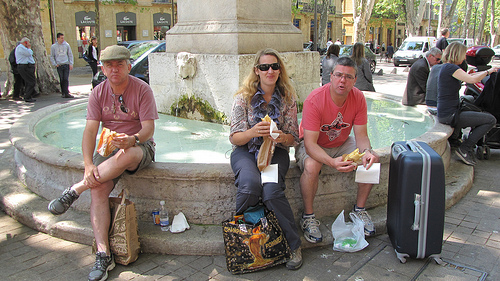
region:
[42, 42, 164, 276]
man in a rusty pink colored shirt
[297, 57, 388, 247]
man in a red shirt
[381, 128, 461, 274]
black and silver plastic suit case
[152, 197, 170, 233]
clear plastic bottle of water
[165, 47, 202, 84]
white stone lion head spitting water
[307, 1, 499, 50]
grouping of trees next to the street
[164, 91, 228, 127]
green algae growing on the fountain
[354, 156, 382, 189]
white paper napkin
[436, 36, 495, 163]
blonde lady wearing all black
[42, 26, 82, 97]
man wearing a long sleeved grey shirt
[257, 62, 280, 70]
dark black sunglasses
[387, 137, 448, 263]
a large black and gray suitcase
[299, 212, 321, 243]
the shoe of a man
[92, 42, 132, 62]
the hat of a man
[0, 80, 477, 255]
a large water fountain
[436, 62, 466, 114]
a woman's short sleeve shirt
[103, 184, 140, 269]
a brown bag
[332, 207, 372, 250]
a white plastic bag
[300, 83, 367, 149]
a man's short sleeve shirt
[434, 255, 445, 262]
the wheel of a suitcase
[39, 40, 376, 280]
three people having lunch outside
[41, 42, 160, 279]
man in pink shirt eating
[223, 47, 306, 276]
woman with decorative shopping bag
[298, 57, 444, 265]
young man with luggage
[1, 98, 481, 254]
base of concrete statue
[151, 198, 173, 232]
water bottle and juice can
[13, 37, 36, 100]
overweight man on cell phone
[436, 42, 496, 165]
young woman resting on statue base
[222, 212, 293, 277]
decorative bag carried by young woman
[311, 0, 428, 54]
shops in background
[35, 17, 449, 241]
group of people sitting down eating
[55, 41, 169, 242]
man sitting down with legs crossed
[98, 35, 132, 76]
brown hat on man's head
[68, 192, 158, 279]
tan backpack behind man's leg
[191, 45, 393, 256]
two people sitting down eating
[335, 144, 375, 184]
sandwich in a hand of a man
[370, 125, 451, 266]
black luggage case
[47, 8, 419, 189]
small fountain structure with water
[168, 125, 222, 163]
water in fountain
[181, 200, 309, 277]
black and yellow purse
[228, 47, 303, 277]
woman wearing sunglasses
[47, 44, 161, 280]
man wearing hat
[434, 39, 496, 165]
woman with short hair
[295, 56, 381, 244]
man eating a sandwich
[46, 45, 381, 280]
three people eating a sandwich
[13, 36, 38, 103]
man with red phone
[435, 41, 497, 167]
woman wearing black shirt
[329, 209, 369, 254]
white bag on the sidewalk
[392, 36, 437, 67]
white car on the street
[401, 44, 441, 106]
man with dark suit